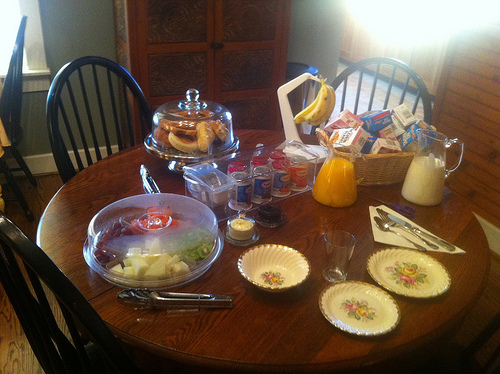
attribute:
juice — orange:
[310, 159, 359, 207]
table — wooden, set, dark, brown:
[33, 125, 483, 372]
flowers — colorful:
[338, 293, 382, 324]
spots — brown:
[321, 94, 329, 103]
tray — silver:
[148, 139, 240, 156]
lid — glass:
[149, 83, 236, 154]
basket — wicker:
[311, 130, 437, 188]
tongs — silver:
[113, 287, 235, 313]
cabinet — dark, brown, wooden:
[111, 0, 291, 151]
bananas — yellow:
[285, 79, 344, 130]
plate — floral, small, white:
[317, 279, 403, 339]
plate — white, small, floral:
[364, 246, 456, 302]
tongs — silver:
[118, 288, 231, 314]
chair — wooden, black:
[40, 47, 154, 185]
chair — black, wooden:
[2, 212, 139, 372]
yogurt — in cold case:
[226, 147, 308, 201]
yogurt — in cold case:
[222, 146, 313, 210]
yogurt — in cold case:
[218, 150, 308, 206]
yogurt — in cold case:
[227, 146, 310, 206]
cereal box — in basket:
[326, 129, 368, 149]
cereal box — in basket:
[325, 124, 371, 155]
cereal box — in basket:
[330, 125, 370, 153]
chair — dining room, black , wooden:
[43, 54, 159, 181]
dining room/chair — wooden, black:
[309, 53, 436, 136]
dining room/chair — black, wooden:
[321, 53, 433, 131]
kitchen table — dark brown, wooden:
[34, 126, 484, 370]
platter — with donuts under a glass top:
[144, 89, 242, 171]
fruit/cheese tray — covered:
[82, 190, 223, 302]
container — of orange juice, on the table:
[313, 136, 361, 211]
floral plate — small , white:
[316, 277, 402, 340]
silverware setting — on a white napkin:
[369, 205, 458, 255]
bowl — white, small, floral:
[235, 240, 313, 295]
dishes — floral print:
[236, 239, 453, 339]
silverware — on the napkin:
[370, 202, 460, 251]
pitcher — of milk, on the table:
[399, 127, 466, 208]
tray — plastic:
[78, 213, 223, 288]